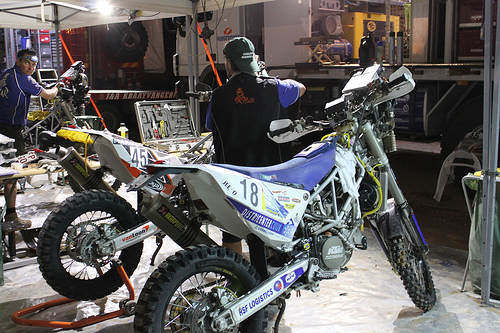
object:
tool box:
[134, 98, 214, 157]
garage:
[0, 0, 500, 332]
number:
[127, 146, 141, 169]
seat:
[210, 158, 307, 191]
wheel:
[130, 240, 271, 332]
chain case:
[205, 245, 316, 331]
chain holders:
[76, 219, 158, 276]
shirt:
[204, 70, 300, 164]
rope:
[82, 142, 91, 174]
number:
[247, 181, 260, 208]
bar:
[5, 294, 68, 315]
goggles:
[18, 52, 42, 62]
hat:
[221, 35, 263, 76]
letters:
[237, 51, 255, 61]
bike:
[55, 36, 441, 332]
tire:
[376, 204, 438, 313]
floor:
[2, 138, 499, 331]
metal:
[388, 180, 408, 213]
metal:
[473, 168, 499, 297]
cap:
[225, 33, 265, 93]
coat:
[201, 75, 306, 163]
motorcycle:
[33, 123, 229, 304]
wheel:
[34, 190, 149, 301]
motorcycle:
[0, 61, 128, 197]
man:
[0, 47, 63, 171]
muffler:
[126, 187, 216, 249]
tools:
[151, 119, 160, 140]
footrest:
[311, 270, 336, 280]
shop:
[0, 0, 499, 332]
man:
[204, 35, 307, 275]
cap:
[217, 30, 262, 83]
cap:
[224, 30, 267, 83]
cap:
[220, 35, 262, 75]